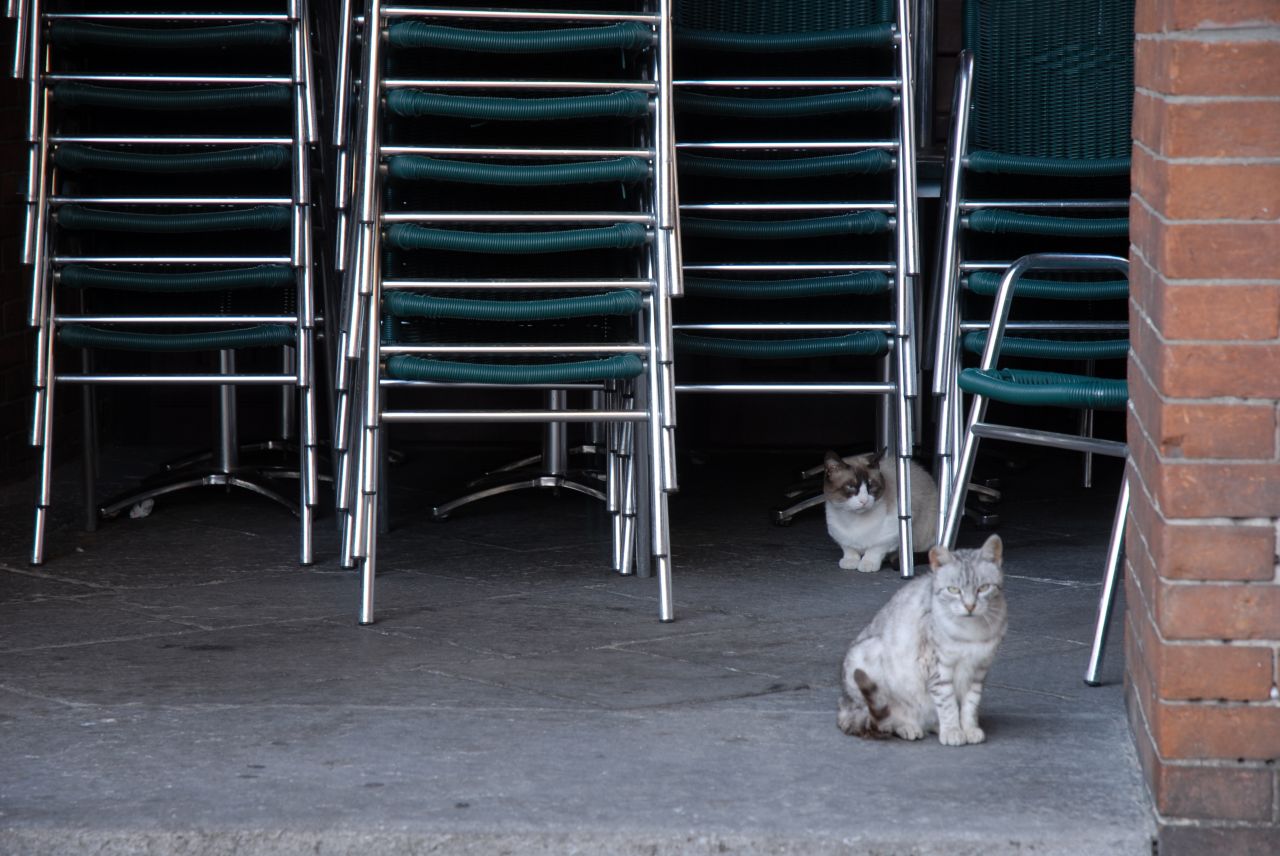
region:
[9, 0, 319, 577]
Stack of green chairs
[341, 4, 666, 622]
stack of green chairs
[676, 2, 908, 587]
Stack of green chairs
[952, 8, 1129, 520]
Stack of green chairs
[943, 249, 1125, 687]
Single green chair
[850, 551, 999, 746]
Gray and white cat sitting on concrete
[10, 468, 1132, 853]
Gray concrete floor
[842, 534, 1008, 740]
Cat with tail is sitting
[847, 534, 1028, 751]
silver cat with dark rings on it's tail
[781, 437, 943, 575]
A white and cream colored cat wears a dark mask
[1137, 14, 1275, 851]
corner made of red brick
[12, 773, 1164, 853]
edge of a concrete step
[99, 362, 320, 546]
chrome base of a table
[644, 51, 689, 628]
chrome legs of stacking chairs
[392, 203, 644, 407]
green seats of stacking chairs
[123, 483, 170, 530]
white crumpled paper caught under a table leg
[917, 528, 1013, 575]
two pointed silver ears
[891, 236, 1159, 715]
one chair sits unstacked behind a brick corner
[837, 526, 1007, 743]
light colored cat with a striped tail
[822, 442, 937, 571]
cat with dark ears sitting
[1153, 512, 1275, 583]
red brick in a wall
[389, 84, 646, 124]
green fabric on a seat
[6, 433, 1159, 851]
light gray concrete floor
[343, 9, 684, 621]
stack of metal and green fabric chairs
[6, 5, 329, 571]
stack of metal and green fabric chairs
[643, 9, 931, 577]
stack of metal and green fabric chairs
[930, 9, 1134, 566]
stack of metal and green fabric chairs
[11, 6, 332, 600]
stack of metal chairs with green wicker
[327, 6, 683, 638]
stack of silver metal and green wicker chairs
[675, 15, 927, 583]
stack of green and silver chairs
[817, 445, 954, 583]
cat is crouched down under chairs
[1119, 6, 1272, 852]
red brick wall with grey mortar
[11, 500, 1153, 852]
grey sidewalk with cracks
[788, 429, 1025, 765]
two cats on a sidewalk